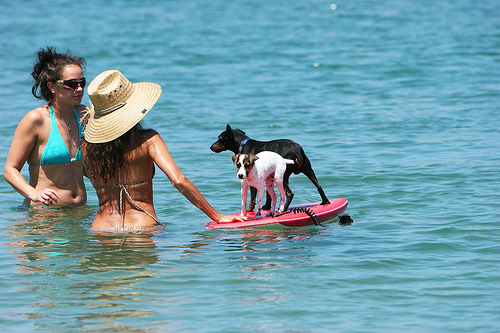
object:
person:
[80, 70, 247, 233]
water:
[1, 1, 499, 331]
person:
[2, 46, 90, 209]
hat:
[82, 70, 163, 144]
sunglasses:
[53, 77, 86, 90]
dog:
[230, 151, 295, 220]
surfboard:
[204, 197, 348, 230]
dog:
[209, 123, 331, 212]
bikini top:
[28, 106, 85, 167]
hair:
[73, 122, 159, 184]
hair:
[29, 45, 87, 107]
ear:
[249, 154, 259, 163]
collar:
[237, 138, 252, 154]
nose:
[238, 174, 243, 179]